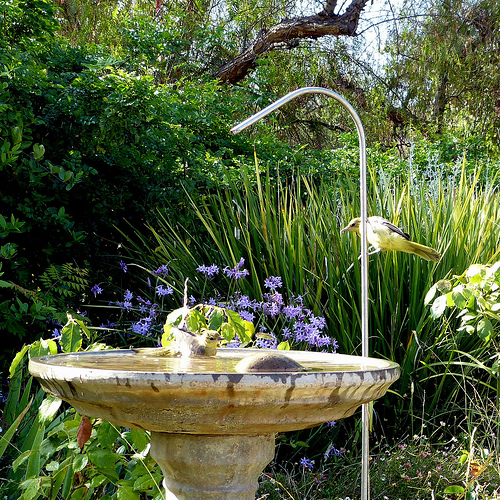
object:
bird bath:
[129, 319, 229, 364]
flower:
[223, 331, 243, 350]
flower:
[263, 276, 283, 291]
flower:
[295, 329, 305, 341]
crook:
[230, 86, 371, 500]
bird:
[129, 320, 225, 359]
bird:
[338, 212, 441, 262]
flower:
[155, 282, 177, 301]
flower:
[115, 259, 133, 278]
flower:
[90, 283, 104, 303]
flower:
[151, 282, 177, 296]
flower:
[235, 293, 256, 310]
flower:
[121, 291, 133, 304]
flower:
[47, 328, 63, 342]